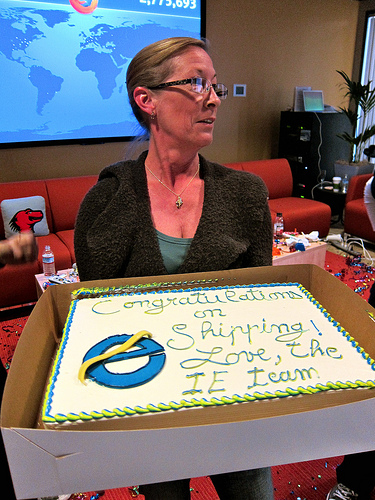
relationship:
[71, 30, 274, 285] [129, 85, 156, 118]
lady has ear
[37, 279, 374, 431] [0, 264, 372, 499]
cake in box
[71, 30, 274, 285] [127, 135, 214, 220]
lady wearing necklace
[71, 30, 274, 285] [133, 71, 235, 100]
lady wearing glasses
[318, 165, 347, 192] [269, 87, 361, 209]
cup on cabinet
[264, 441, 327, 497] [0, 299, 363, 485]
confetti on carpet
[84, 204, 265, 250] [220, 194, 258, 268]
sweater blackh grey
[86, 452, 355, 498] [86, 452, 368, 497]
confetti on floor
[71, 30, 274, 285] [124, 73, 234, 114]
lady wearing glasses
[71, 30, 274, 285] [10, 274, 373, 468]
lady holding box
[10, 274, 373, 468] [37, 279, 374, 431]
box with cake